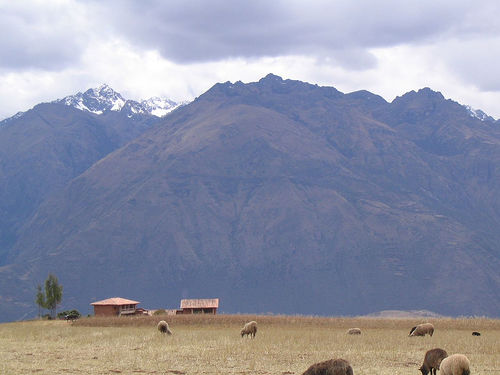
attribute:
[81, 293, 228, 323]
house — small, orange, wooden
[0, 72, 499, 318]
mountains — capped, tall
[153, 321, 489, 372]
sheep — white, light, grazing, standing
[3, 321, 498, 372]
grass — brown, dry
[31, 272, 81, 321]
tree — small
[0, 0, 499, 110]
sky — cloudy